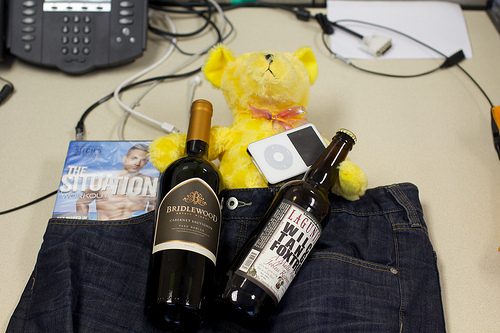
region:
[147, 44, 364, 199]
yellow teddy bear next to the bottles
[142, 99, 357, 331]
two wine bottes on blue jeans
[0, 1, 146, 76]
telephone next to the cables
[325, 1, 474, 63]
paper under the cables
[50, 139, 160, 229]
DVD case in jeans pocket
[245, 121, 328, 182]
4th generation Ipod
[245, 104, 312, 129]
red bow tie on teddy bear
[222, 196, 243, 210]
silver botton on blue jeans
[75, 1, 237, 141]
black, white and grey cables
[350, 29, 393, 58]
DVI-D cable on top of paper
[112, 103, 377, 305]
two bottles of wine on table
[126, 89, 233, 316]
regular size bottle of wine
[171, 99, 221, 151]
golden wrapping on wine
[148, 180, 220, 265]
black wine label on bottle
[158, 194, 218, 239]
white writing on wine bottle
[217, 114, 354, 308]
bottle of beer on table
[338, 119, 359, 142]
metal bottle cap on beer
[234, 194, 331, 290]
white label on beer bottle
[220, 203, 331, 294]
red and black writing on bottle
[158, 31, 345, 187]
yellow teddy bear on table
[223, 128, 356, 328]
a bottle of craft beer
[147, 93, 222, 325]
a bottle of red wine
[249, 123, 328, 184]
a white iPod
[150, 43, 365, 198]
a yellow teddy bear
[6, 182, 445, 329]
a pair of blue jeans on the table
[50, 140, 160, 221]
a workout DVD in plastic wrap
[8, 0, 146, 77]
a black telephone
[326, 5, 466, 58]
a white piece of paper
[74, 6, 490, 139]
several black and white computer cords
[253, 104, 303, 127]
pink bow on the yellow bear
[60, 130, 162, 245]
the situation workout dvd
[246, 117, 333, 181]
white ipod with dark screen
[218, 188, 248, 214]
silver rivet on blue jeans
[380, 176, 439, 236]
dark blue belt loop on jeans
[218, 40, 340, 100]
yellow head of stuffed teddybear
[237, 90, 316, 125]
orange bow tie on teddy bear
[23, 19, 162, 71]
black phone in upper left of photo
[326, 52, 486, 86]
dark black cords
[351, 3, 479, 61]
white paper with cords on it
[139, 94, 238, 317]
dark bridlewood wine bottle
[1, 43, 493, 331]
items laid out on a desk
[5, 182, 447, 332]
the top portion of an article of blue denim clothing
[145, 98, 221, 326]
bottle of wine with a gold colored top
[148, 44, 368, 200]
a bright yellow teddy bear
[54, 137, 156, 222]
DVD with an image of a man on the cover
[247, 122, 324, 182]
a white MP3 player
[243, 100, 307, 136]
bow-tie attached to bear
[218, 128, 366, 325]
brown bottle next to bear's paw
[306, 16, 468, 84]
black and white cord connectors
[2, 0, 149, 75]
a dark grey telephone